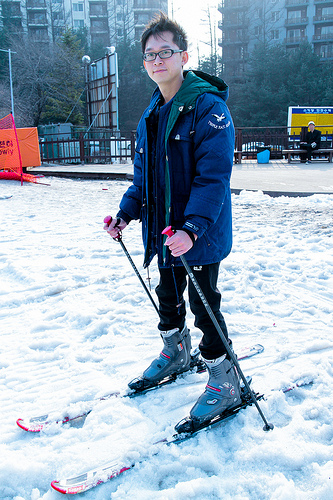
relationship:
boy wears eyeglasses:
[106, 9, 247, 427] [139, 47, 188, 64]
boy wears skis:
[106, 9, 247, 427] [11, 336, 320, 496]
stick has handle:
[156, 222, 296, 440] [158, 225, 176, 246]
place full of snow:
[3, 0, 330, 494] [3, 166, 332, 497]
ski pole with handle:
[103, 212, 163, 325] [101, 214, 120, 232]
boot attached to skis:
[184, 347, 245, 425] [49, 355, 314, 496]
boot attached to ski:
[143, 328, 193, 385] [18, 338, 270, 440]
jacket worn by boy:
[114, 62, 247, 276] [106, 9, 247, 427]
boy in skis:
[106, 9, 247, 427] [11, 336, 320, 496]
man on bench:
[296, 118, 322, 162] [280, 132, 332, 160]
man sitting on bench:
[296, 118, 322, 162] [280, 132, 332, 160]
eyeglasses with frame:
[144, 43, 186, 64] [143, 44, 188, 63]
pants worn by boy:
[149, 251, 230, 352] [106, 9, 247, 427]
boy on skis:
[106, 9, 247, 427] [11, 336, 320, 496]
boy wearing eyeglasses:
[106, 9, 247, 427] [139, 47, 188, 64]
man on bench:
[299, 120, 322, 166] [280, 132, 332, 160]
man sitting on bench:
[299, 120, 322, 166] [280, 132, 332, 160]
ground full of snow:
[8, 144, 332, 493] [3, 166, 332, 497]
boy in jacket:
[106, 12, 246, 426] [114, 62, 247, 276]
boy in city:
[106, 12, 246, 426] [10, 3, 332, 176]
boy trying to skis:
[106, 12, 246, 426] [49, 355, 314, 496]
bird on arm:
[213, 108, 229, 123] [179, 94, 239, 238]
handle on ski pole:
[158, 225, 176, 246] [103, 212, 163, 325]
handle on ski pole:
[101, 214, 120, 232] [103, 212, 163, 325]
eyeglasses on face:
[139, 47, 188, 64] [142, 25, 182, 89]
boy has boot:
[106, 9, 247, 427] [188, 345, 244, 423]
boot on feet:
[188, 345, 244, 423] [139, 343, 253, 418]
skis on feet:
[11, 336, 320, 496] [139, 343, 253, 418]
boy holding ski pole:
[106, 9, 247, 427] [103, 212, 163, 325]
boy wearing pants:
[106, 9, 247, 427] [149, 251, 230, 352]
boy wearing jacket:
[106, 9, 247, 427] [114, 66, 238, 273]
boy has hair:
[106, 9, 247, 427] [142, 17, 193, 55]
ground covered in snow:
[8, 144, 332, 493] [3, 166, 332, 497]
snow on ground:
[3, 166, 332, 497] [8, 144, 332, 493]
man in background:
[299, 120, 322, 166] [5, 0, 332, 225]